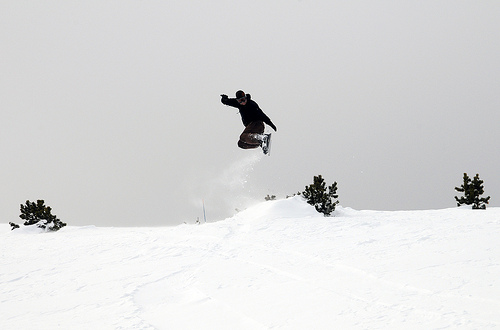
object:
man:
[220, 89, 277, 149]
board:
[266, 133, 272, 155]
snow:
[180, 153, 264, 202]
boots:
[258, 135, 269, 153]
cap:
[236, 89, 246, 98]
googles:
[237, 95, 247, 103]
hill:
[1, 209, 498, 329]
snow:
[238, 193, 354, 220]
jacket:
[222, 93, 272, 125]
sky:
[2, 1, 499, 226]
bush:
[288, 174, 340, 219]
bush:
[454, 173, 493, 209]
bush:
[9, 199, 64, 234]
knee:
[241, 134, 247, 141]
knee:
[238, 140, 244, 147]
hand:
[222, 93, 229, 101]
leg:
[241, 120, 266, 145]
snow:
[20, 219, 56, 230]